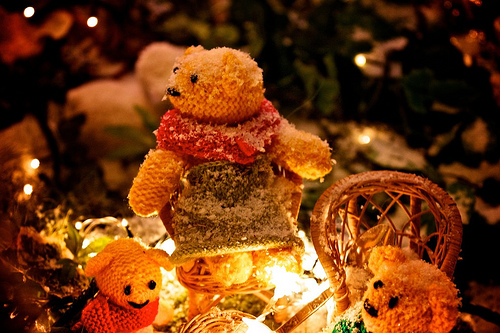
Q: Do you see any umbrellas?
A: No, there are no umbrellas.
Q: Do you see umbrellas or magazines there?
A: No, there are no umbrellas or magazines.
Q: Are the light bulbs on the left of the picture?
A: Yes, the light bulbs are on the left of the image.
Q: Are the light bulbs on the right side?
A: No, the light bulbs are on the left of the image.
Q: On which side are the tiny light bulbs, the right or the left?
A: The light bulbs are on the left of the image.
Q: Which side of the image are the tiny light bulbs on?
A: The bulbs are on the left of the image.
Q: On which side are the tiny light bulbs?
A: The bulbs are on the left of the image.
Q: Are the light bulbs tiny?
A: Yes, the light bulbs are tiny.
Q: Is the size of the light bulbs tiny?
A: Yes, the light bulbs are tiny.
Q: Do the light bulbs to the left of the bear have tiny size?
A: Yes, the bulbs are tiny.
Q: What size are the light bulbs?
A: The light bulbs are tiny.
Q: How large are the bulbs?
A: The bulbs are tiny.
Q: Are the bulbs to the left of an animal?
A: Yes, the bulbs are to the left of an animal.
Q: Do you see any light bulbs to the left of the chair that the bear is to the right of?
A: Yes, there are light bulbs to the left of the chair.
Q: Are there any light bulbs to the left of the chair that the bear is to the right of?
A: Yes, there are light bulbs to the left of the chair.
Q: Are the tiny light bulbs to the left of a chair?
A: Yes, the bulbs are to the left of a chair.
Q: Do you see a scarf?
A: Yes, there is a scarf.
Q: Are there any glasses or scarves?
A: Yes, there is a scarf.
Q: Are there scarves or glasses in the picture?
A: Yes, there is a scarf.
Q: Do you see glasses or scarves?
A: Yes, there is a scarf.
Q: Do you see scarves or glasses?
A: Yes, there is a scarf.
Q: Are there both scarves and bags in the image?
A: No, there is a scarf but no bags.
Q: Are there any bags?
A: No, there are no bags.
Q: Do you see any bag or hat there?
A: No, there are no bags or hats.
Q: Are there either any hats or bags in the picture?
A: No, there are no bags or hats.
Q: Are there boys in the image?
A: No, there are no boys.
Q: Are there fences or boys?
A: No, there are no boys or fences.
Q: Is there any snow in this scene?
A: Yes, there is snow.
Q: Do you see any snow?
A: Yes, there is snow.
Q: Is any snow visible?
A: Yes, there is snow.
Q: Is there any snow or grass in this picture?
A: Yes, there is snow.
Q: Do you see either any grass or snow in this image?
A: Yes, there is snow.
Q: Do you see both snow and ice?
A: No, there is snow but no ice.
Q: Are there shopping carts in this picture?
A: No, there are no shopping carts.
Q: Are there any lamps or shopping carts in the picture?
A: No, there are no shopping carts or lamps.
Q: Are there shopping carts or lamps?
A: No, there are no shopping carts or lamps.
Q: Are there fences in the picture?
A: No, there are no fences.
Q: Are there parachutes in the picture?
A: No, there are no parachutes.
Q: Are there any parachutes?
A: No, there are no parachutes.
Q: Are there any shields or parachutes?
A: No, there are no parachutes or shields.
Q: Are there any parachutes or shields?
A: No, there are no parachutes or shields.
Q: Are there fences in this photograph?
A: No, there are no fences.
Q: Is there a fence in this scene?
A: No, there are no fences.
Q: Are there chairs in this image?
A: Yes, there is a chair.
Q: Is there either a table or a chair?
A: Yes, there is a chair.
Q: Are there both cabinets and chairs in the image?
A: No, there is a chair but no cabinets.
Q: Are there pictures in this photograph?
A: No, there are no pictures.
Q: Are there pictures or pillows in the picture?
A: No, there are no pictures or pillows.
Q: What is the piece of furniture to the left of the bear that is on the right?
A: The piece of furniture is a chair.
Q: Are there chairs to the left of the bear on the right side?
A: Yes, there is a chair to the left of the bear.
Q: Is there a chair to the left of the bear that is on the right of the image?
A: Yes, there is a chair to the left of the bear.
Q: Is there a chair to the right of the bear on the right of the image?
A: No, the chair is to the left of the bear.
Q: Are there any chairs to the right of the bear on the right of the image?
A: No, the chair is to the left of the bear.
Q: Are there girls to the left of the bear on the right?
A: No, there is a chair to the left of the bear.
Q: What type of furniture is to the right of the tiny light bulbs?
A: The piece of furniture is a chair.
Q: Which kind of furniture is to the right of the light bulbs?
A: The piece of furniture is a chair.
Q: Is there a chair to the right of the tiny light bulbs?
A: Yes, there is a chair to the right of the light bulbs.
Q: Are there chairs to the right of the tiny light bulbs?
A: Yes, there is a chair to the right of the light bulbs.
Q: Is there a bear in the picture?
A: Yes, there is a bear.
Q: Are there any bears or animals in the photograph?
A: Yes, there is a bear.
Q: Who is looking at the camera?
A: The bear is looking at the camera.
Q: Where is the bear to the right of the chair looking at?
A: The bear is looking at the camera.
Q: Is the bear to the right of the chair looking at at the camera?
A: Yes, the bear is looking at the camera.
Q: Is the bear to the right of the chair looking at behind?
A: No, the bear is looking at the camera.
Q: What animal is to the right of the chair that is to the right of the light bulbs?
A: The animal is a bear.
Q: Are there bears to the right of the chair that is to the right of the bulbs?
A: Yes, there is a bear to the right of the chair.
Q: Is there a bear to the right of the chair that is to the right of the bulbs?
A: Yes, there is a bear to the right of the chair.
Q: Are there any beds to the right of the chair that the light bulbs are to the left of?
A: No, there is a bear to the right of the chair.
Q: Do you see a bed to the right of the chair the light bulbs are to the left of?
A: No, there is a bear to the right of the chair.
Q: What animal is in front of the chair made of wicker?
A: The bear is in front of the chair.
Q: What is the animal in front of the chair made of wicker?
A: The animal is a bear.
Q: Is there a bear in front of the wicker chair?
A: Yes, there is a bear in front of the chair.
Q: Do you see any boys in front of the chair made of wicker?
A: No, there is a bear in front of the chair.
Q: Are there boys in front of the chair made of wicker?
A: No, there is a bear in front of the chair.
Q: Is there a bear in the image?
A: Yes, there is a bear.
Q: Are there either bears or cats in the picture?
A: Yes, there is a bear.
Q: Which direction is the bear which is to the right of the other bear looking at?
A: The bear is looking at the camera.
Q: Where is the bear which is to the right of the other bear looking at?
A: The bear is looking at the camera.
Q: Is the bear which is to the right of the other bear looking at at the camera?
A: Yes, the bear is looking at the camera.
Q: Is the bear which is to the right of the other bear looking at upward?
A: No, the bear is looking at the camera.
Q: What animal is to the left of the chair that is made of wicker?
A: The animal is a bear.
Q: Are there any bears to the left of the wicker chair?
A: Yes, there is a bear to the left of the chair.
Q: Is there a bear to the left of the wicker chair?
A: Yes, there is a bear to the left of the chair.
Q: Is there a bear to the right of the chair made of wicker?
A: No, the bear is to the left of the chair.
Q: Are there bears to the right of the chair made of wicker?
A: No, the bear is to the left of the chair.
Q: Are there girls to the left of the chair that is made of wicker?
A: No, there is a bear to the left of the chair.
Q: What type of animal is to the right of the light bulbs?
A: The animal is a bear.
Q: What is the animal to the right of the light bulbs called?
A: The animal is a bear.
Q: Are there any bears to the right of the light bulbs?
A: Yes, there is a bear to the right of the light bulbs.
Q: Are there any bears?
A: Yes, there is a bear.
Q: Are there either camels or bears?
A: Yes, there is a bear.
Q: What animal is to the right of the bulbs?
A: The animal is a bear.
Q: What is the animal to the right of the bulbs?
A: The animal is a bear.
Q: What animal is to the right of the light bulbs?
A: The animal is a bear.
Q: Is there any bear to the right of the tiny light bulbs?
A: Yes, there is a bear to the right of the light bulbs.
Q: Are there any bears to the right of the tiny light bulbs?
A: Yes, there is a bear to the right of the light bulbs.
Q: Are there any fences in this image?
A: No, there are no fences.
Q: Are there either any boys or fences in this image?
A: No, there are no fences or boys.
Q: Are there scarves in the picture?
A: Yes, there is a scarf.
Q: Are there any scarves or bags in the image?
A: Yes, there is a scarf.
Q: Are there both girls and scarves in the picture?
A: No, there is a scarf but no girls.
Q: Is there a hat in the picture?
A: No, there are no hats.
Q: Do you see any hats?
A: No, there are no hats.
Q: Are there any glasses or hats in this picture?
A: No, there are no hats or glasses.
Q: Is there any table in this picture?
A: Yes, there is a table.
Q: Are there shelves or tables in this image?
A: Yes, there is a table.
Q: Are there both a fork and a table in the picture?
A: No, there is a table but no forks.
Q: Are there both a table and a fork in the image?
A: No, there is a table but no forks.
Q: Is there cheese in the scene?
A: No, there is no cheese.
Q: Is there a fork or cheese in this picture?
A: No, there are no cheese or forks.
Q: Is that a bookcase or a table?
A: That is a table.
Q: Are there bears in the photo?
A: Yes, there is a bear.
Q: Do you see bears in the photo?
A: Yes, there is a bear.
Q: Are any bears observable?
A: Yes, there is a bear.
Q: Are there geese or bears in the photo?
A: Yes, there is a bear.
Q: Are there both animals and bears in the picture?
A: Yes, there are both a bear and animals.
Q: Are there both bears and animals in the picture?
A: Yes, there are both a bear and animals.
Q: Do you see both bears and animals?
A: Yes, there are both a bear and animals.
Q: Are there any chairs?
A: Yes, there is a chair.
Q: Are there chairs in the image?
A: Yes, there is a chair.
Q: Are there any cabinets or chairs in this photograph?
A: Yes, there is a chair.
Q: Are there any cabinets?
A: No, there are no cabinets.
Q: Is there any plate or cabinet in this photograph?
A: No, there are no cabinets or plates.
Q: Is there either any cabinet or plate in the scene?
A: No, there are no cabinets or plates.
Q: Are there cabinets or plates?
A: No, there are no cabinets or plates.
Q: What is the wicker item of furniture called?
A: The piece of furniture is a chair.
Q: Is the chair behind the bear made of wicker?
A: Yes, the chair is made of wicker.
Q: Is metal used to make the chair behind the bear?
A: No, the chair is made of wicker.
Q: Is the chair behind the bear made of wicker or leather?
A: The chair is made of wicker.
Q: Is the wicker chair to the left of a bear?
A: No, the chair is to the right of a bear.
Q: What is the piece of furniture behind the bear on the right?
A: The piece of furniture is a chair.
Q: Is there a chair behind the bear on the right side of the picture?
A: Yes, there is a chair behind the bear.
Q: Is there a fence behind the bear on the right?
A: No, there is a chair behind the bear.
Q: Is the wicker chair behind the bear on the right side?
A: Yes, the chair is behind the bear.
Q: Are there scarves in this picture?
A: Yes, there is a scarf.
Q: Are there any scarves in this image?
A: Yes, there is a scarf.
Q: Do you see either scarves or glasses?
A: Yes, there is a scarf.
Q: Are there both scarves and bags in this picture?
A: No, there is a scarf but no bags.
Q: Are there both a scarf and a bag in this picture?
A: No, there is a scarf but no bags.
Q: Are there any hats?
A: No, there are no hats.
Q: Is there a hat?
A: No, there are no hats.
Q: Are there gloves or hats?
A: No, there are no hats or gloves.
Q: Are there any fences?
A: No, there are no fences.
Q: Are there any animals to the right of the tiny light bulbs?
A: Yes, there is an animal to the right of the light bulbs.